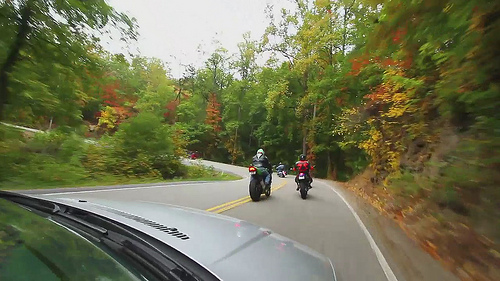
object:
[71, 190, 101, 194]
line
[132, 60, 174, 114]
trees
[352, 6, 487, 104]
leaves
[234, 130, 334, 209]
objects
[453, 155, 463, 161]
?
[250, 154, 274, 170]
jacket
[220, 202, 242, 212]
yellow line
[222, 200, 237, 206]
yellow line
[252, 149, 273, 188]
biker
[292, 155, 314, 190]
biker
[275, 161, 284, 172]
biker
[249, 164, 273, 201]
bike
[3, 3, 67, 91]
tree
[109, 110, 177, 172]
bush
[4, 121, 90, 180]
bush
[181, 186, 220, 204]
road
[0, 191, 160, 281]
windshield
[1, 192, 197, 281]
wipers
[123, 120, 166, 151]
green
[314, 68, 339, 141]
green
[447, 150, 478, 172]
green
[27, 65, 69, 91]
green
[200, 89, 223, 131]
leaves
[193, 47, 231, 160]
tree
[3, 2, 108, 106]
leaves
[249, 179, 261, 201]
tire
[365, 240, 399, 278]
line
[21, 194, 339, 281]
hood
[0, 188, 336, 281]
car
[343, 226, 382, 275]
ground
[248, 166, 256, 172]
back headlight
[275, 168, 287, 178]
motorcycle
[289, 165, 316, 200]
motorcycle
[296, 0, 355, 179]
trees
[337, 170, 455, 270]
bananas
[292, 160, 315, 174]
jacket